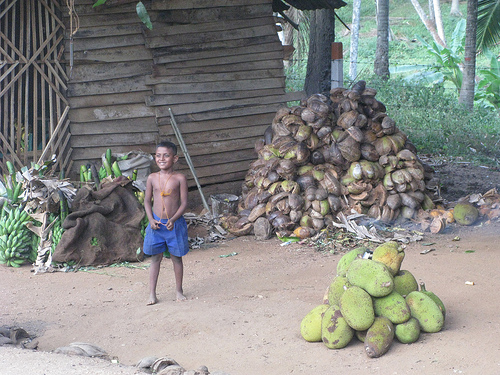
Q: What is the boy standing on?
A: Dirt.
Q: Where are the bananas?
A: On the ground on the far left.